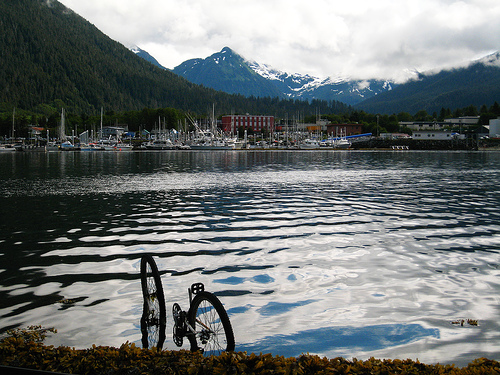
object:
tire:
[136, 254, 168, 347]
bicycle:
[137, 255, 235, 355]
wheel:
[186, 290, 235, 353]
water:
[0, 144, 498, 370]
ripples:
[223, 243, 260, 278]